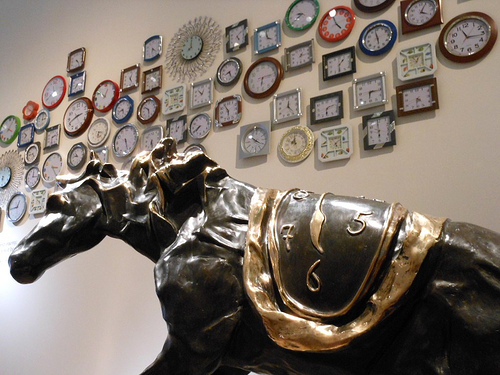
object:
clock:
[356, 16, 398, 55]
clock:
[50, 92, 98, 136]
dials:
[64, 108, 89, 128]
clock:
[60, 45, 87, 71]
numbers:
[300, 250, 328, 297]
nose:
[6, 241, 54, 283]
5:
[341, 203, 371, 234]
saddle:
[225, 176, 445, 367]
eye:
[45, 188, 71, 217]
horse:
[8, 127, 494, 372]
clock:
[243, 56, 290, 98]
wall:
[395, 108, 493, 194]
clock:
[358, 107, 400, 152]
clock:
[313, 2, 354, 42]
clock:
[282, 2, 319, 31]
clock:
[33, 111, 53, 132]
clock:
[160, 11, 229, 82]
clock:
[182, 108, 215, 142]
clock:
[111, 122, 138, 158]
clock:
[28, 73, 65, 109]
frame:
[38, 71, 67, 109]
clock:
[241, 176, 447, 356]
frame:
[434, 10, 497, 70]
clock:
[0, 110, 22, 147]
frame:
[1, 112, 24, 147]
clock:
[81, 82, 115, 110]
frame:
[83, 77, 123, 115]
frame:
[105, 95, 139, 126]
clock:
[109, 96, 135, 129]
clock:
[314, 122, 351, 163]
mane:
[94, 160, 152, 210]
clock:
[389, 33, 442, 80]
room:
[3, 0, 493, 373]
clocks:
[238, 121, 268, 160]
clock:
[435, 6, 497, 68]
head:
[8, 161, 119, 282]